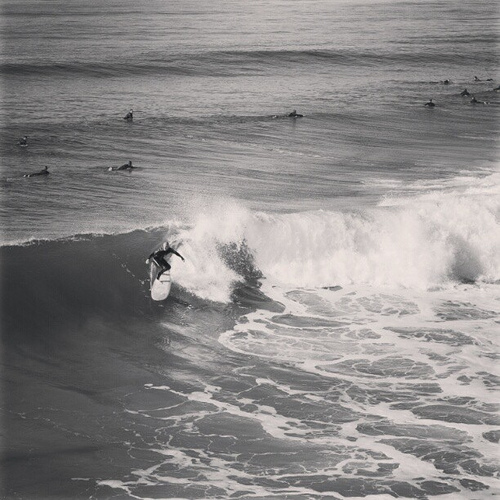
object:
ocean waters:
[0, 0, 500, 500]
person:
[108, 161, 139, 171]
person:
[17, 136, 29, 147]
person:
[124, 109, 133, 122]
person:
[19, 165, 51, 178]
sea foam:
[209, 182, 500, 288]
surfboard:
[151, 272, 175, 301]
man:
[145, 241, 185, 281]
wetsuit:
[148, 247, 185, 280]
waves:
[0, 167, 500, 500]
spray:
[3, 170, 499, 498]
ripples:
[70, 330, 500, 500]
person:
[471, 96, 489, 104]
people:
[425, 98, 436, 107]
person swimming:
[461, 88, 470, 95]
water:
[0, 3, 500, 498]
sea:
[0, 2, 499, 499]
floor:
[0, 0, 499, 142]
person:
[288, 109, 303, 117]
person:
[443, 79, 450, 84]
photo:
[0, 0, 500, 500]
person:
[491, 84, 500, 93]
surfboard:
[107, 167, 144, 174]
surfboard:
[281, 114, 306, 119]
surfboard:
[19, 171, 50, 180]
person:
[24, 156, 55, 175]